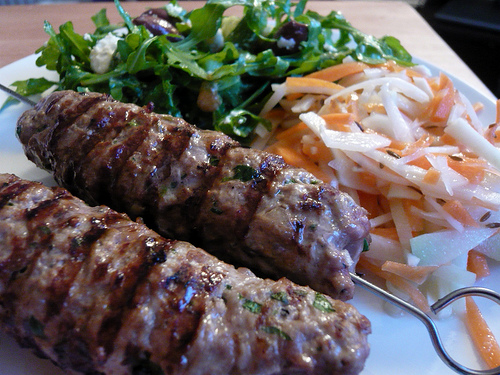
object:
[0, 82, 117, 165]
meat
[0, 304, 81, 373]
meat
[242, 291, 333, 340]
seasoning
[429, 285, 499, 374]
handle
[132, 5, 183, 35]
olive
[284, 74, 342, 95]
carrot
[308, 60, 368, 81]
carrot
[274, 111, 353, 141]
carrot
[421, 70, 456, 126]
carrot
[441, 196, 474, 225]
carrot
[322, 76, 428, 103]
cabbage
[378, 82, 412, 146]
cabbage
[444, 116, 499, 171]
cabbage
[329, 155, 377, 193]
cabbage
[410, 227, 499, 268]
cabbage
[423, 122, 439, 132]
fennel seed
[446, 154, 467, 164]
fennel seed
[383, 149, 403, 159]
fennel seed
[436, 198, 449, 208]
fennel seed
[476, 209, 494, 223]
fennel seed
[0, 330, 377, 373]
steak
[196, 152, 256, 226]
steak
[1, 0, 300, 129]
salad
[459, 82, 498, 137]
carrot strips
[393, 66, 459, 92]
strips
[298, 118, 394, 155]
strips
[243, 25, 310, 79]
strips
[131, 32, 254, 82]
strips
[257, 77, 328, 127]
strips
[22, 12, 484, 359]
plate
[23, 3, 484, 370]
meal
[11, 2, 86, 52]
table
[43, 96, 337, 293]
lamb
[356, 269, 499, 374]
skewer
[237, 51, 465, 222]
salad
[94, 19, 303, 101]
greens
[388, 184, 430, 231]
carrots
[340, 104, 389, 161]
slices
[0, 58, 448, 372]
skewer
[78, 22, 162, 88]
cheese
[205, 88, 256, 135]
vegetables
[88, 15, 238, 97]
these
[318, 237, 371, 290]
meat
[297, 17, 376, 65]
pile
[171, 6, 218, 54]
leaves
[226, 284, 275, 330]
specks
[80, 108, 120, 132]
meat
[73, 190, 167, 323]
mark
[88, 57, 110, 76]
pile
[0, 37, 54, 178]
plate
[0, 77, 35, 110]
skewer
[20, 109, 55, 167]
meat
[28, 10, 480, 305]
food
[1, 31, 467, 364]
plate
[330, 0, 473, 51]
table